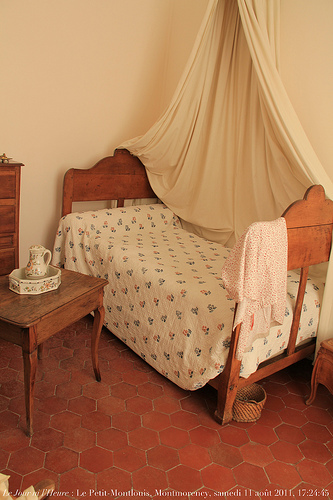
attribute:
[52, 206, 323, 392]
bedding — vintage, flowered, white, pink, floral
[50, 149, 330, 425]
bed — multi-colored, wooden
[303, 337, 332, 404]
side table — small, wooden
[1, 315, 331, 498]
floor — brown, red, maroon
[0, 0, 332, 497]
bedroom — white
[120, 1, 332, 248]
curtains — white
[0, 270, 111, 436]
table — wooden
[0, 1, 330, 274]
wall — cream colored, light yellow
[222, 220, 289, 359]
blanket — pink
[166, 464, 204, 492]
tile — red, hexagonal shaped